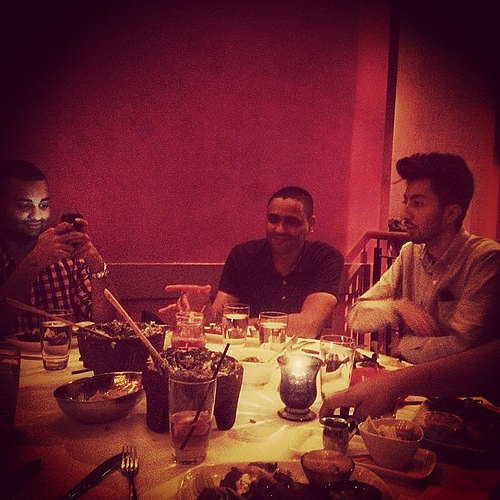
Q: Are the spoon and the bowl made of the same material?
A: No, the spoon is made of wood and the bowl is made of metal.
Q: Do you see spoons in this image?
A: Yes, there is a spoon.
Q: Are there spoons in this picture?
A: Yes, there is a spoon.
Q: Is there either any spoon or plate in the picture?
A: Yes, there is a spoon.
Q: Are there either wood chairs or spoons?
A: Yes, there is a wood spoon.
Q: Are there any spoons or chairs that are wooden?
A: Yes, the spoon is wooden.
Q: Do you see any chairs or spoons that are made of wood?
A: Yes, the spoon is made of wood.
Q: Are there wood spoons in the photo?
A: Yes, there is a wood spoon.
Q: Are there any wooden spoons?
A: Yes, there is a wood spoon.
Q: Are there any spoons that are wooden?
A: Yes, there is a spoon that is wooden.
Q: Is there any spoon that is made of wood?
A: Yes, there is a spoon that is made of wood.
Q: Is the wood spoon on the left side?
A: Yes, the spoon is on the left of the image.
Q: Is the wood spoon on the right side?
A: No, the spoon is on the left of the image.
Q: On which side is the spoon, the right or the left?
A: The spoon is on the left of the image.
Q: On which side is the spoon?
A: The spoon is on the left of the image.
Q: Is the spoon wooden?
A: Yes, the spoon is wooden.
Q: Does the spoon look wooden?
A: Yes, the spoon is wooden.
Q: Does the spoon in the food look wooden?
A: Yes, the spoon is wooden.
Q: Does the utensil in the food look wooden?
A: Yes, the spoon is wooden.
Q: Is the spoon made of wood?
A: Yes, the spoon is made of wood.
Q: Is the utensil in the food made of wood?
A: Yes, the spoon is made of wood.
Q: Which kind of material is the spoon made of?
A: The spoon is made of wood.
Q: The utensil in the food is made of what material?
A: The spoon is made of wood.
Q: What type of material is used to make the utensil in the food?
A: The spoon is made of wood.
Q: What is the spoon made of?
A: The spoon is made of wood.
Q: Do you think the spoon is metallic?
A: No, the spoon is wooden.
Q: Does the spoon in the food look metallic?
A: No, the spoon is wooden.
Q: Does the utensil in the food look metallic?
A: No, the spoon is wooden.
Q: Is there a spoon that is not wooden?
A: No, there is a spoon but it is wooden.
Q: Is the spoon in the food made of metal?
A: No, the spoon is made of wood.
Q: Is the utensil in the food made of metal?
A: No, the spoon is made of wood.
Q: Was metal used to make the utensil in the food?
A: No, the spoon is made of wood.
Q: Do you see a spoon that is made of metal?
A: No, there is a spoon but it is made of wood.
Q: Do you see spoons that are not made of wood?
A: No, there is a spoon but it is made of wood.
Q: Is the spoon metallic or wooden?
A: The spoon is wooden.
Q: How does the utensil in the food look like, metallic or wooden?
A: The spoon is wooden.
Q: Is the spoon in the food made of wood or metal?
A: The spoon is made of wood.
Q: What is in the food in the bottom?
A: The spoon is in the food.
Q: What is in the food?
A: The spoon is in the food.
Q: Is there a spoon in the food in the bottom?
A: Yes, there is a spoon in the food.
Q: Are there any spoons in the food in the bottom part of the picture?
A: Yes, there is a spoon in the food.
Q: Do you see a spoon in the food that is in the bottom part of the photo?
A: Yes, there is a spoon in the food.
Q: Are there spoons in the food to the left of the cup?
A: Yes, there is a spoon in the food.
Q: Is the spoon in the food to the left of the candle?
A: Yes, the spoon is in the food.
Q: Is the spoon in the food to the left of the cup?
A: Yes, the spoon is in the food.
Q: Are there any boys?
A: No, there are no boys.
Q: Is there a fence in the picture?
A: No, there are no fences.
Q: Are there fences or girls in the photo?
A: No, there are no fences or girls.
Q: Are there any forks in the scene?
A: Yes, there is a fork.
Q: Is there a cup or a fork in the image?
A: Yes, there is a fork.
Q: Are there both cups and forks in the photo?
A: Yes, there are both a fork and a cup.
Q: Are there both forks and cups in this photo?
A: Yes, there are both a fork and a cup.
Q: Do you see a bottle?
A: No, there are no bottles.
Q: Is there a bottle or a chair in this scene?
A: No, there are no bottles or chairs.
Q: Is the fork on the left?
A: Yes, the fork is on the left of the image.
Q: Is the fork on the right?
A: No, the fork is on the left of the image.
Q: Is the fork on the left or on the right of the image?
A: The fork is on the left of the image.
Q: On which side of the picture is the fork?
A: The fork is on the left of the image.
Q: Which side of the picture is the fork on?
A: The fork is on the left of the image.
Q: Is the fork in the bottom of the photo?
A: Yes, the fork is in the bottom of the image.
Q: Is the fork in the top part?
A: No, the fork is in the bottom of the image.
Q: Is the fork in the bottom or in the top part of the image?
A: The fork is in the bottom of the image.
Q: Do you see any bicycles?
A: No, there are no bicycles.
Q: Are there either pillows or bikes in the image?
A: No, there are no bikes or pillows.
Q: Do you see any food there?
A: Yes, there is food.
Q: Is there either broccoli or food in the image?
A: Yes, there is food.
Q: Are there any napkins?
A: No, there are no napkins.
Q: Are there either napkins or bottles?
A: No, there are no napkins or bottles.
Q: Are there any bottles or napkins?
A: No, there are no napkins or bottles.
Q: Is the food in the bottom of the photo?
A: Yes, the food is in the bottom of the image.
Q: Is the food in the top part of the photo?
A: No, the food is in the bottom of the image.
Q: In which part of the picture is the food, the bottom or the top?
A: The food is in the bottom of the image.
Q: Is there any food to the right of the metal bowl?
A: Yes, there is food to the right of the bowl.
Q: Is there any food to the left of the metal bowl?
A: No, the food is to the right of the bowl.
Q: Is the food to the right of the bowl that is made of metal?
A: Yes, the food is to the right of the bowl.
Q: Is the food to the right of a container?
A: No, the food is to the right of the bowl.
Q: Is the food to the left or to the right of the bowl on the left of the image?
A: The food is to the right of the bowl.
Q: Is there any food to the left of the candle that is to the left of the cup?
A: Yes, there is food to the left of the candle.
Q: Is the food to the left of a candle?
A: Yes, the food is to the left of a candle.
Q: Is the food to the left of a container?
A: No, the food is to the left of a candle.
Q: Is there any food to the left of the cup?
A: Yes, there is food to the left of the cup.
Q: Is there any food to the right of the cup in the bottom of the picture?
A: No, the food is to the left of the cup.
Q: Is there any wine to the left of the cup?
A: No, there is food to the left of the cup.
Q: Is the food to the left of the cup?
A: Yes, the food is to the left of the cup.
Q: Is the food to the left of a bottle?
A: No, the food is to the left of the cup.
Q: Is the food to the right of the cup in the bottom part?
A: No, the food is to the left of the cup.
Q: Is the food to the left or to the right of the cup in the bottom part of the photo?
A: The food is to the left of the cup.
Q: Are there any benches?
A: No, there are no benches.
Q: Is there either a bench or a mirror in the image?
A: No, there are no benches or mirrors.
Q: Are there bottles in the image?
A: No, there are no bottles.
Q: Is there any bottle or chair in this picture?
A: No, there are no bottles or chairs.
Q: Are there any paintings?
A: No, there are no paintings.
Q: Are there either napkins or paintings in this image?
A: No, there are no paintings or napkins.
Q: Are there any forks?
A: Yes, there is a fork.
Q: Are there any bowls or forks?
A: Yes, there is a fork.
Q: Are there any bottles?
A: No, there are no bottles.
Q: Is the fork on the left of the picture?
A: Yes, the fork is on the left of the image.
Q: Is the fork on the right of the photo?
A: No, the fork is on the left of the image.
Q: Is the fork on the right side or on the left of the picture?
A: The fork is on the left of the image.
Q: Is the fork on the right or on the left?
A: The fork is on the left of the image.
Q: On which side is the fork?
A: The fork is on the left of the image.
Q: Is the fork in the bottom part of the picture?
A: Yes, the fork is in the bottom of the image.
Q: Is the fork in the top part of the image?
A: No, the fork is in the bottom of the image.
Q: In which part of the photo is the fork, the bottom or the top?
A: The fork is in the bottom of the image.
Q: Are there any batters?
A: No, there are no batters.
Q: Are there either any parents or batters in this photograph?
A: No, there are no batters or parents.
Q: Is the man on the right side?
A: Yes, the man is on the right of the image.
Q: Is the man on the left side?
A: No, the man is on the right of the image.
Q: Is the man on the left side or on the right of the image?
A: The man is on the right of the image.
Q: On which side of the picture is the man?
A: The man is on the right of the image.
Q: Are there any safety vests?
A: No, there are no safety vests.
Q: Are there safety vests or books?
A: No, there are no safety vests or books.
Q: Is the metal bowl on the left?
A: Yes, the bowl is on the left of the image.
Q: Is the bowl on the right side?
A: No, the bowl is on the left of the image.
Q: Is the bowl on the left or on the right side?
A: The bowl is on the left of the image.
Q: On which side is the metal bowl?
A: The bowl is on the left of the image.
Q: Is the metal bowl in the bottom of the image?
A: Yes, the bowl is in the bottom of the image.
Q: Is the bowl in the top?
A: No, the bowl is in the bottom of the image.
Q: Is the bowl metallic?
A: Yes, the bowl is metallic.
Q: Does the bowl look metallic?
A: Yes, the bowl is metallic.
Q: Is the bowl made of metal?
A: Yes, the bowl is made of metal.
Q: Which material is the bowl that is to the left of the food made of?
A: The bowl is made of metal.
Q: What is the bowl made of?
A: The bowl is made of metal.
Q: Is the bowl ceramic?
A: No, the bowl is metallic.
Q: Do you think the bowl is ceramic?
A: No, the bowl is metallic.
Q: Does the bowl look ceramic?
A: No, the bowl is metallic.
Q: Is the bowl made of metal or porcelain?
A: The bowl is made of metal.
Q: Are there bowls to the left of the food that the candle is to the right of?
A: Yes, there is a bowl to the left of the food.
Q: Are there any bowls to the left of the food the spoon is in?
A: Yes, there is a bowl to the left of the food.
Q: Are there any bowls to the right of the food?
A: No, the bowl is to the left of the food.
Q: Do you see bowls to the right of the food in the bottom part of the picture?
A: No, the bowl is to the left of the food.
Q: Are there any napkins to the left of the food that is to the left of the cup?
A: No, there is a bowl to the left of the food.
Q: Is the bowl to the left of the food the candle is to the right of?
A: Yes, the bowl is to the left of the food.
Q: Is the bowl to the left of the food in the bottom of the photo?
A: Yes, the bowl is to the left of the food.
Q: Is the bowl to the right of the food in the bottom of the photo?
A: No, the bowl is to the left of the food.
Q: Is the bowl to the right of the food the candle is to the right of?
A: No, the bowl is to the left of the food.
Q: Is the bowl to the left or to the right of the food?
A: The bowl is to the left of the food.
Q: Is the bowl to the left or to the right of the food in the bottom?
A: The bowl is to the left of the food.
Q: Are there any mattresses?
A: No, there are no mattresses.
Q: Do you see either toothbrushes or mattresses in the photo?
A: No, there are no mattresses or toothbrushes.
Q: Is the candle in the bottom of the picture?
A: Yes, the candle is in the bottom of the image.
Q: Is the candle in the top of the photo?
A: No, the candle is in the bottom of the image.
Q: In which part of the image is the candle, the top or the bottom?
A: The candle is in the bottom of the image.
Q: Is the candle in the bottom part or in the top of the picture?
A: The candle is in the bottom of the image.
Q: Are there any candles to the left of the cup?
A: Yes, there is a candle to the left of the cup.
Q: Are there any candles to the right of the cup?
A: No, the candle is to the left of the cup.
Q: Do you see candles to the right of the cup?
A: No, the candle is to the left of the cup.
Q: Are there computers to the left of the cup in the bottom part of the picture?
A: No, there is a candle to the left of the cup.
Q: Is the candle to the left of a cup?
A: Yes, the candle is to the left of a cup.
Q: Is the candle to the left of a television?
A: No, the candle is to the left of a cup.